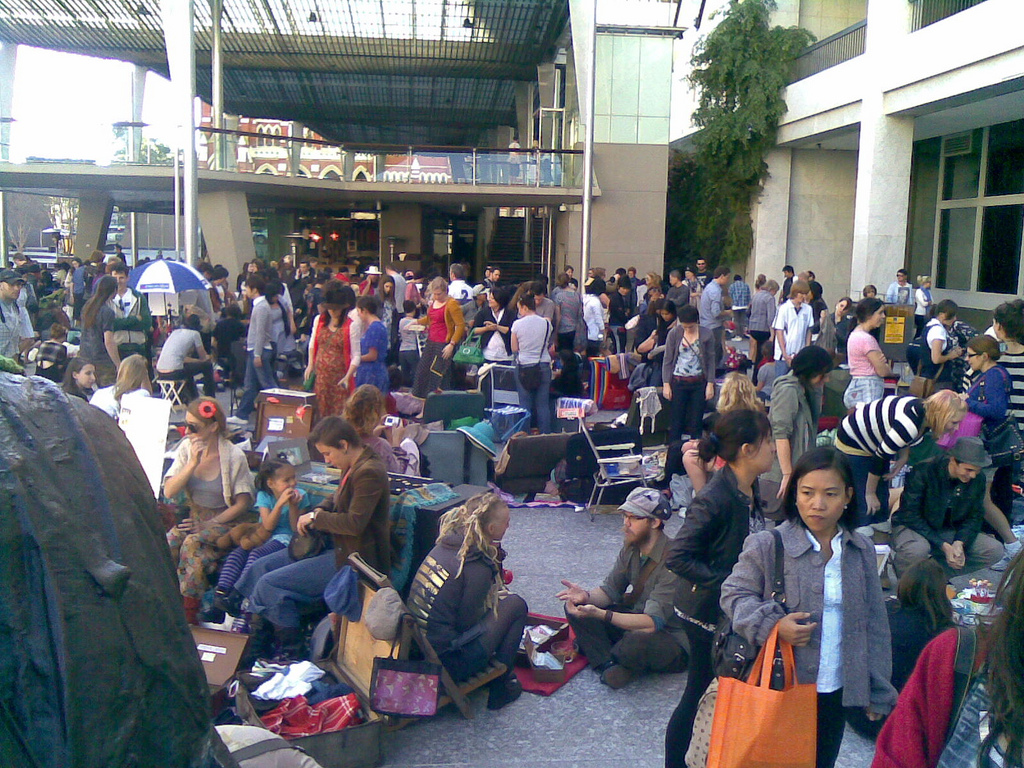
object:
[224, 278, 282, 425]
person